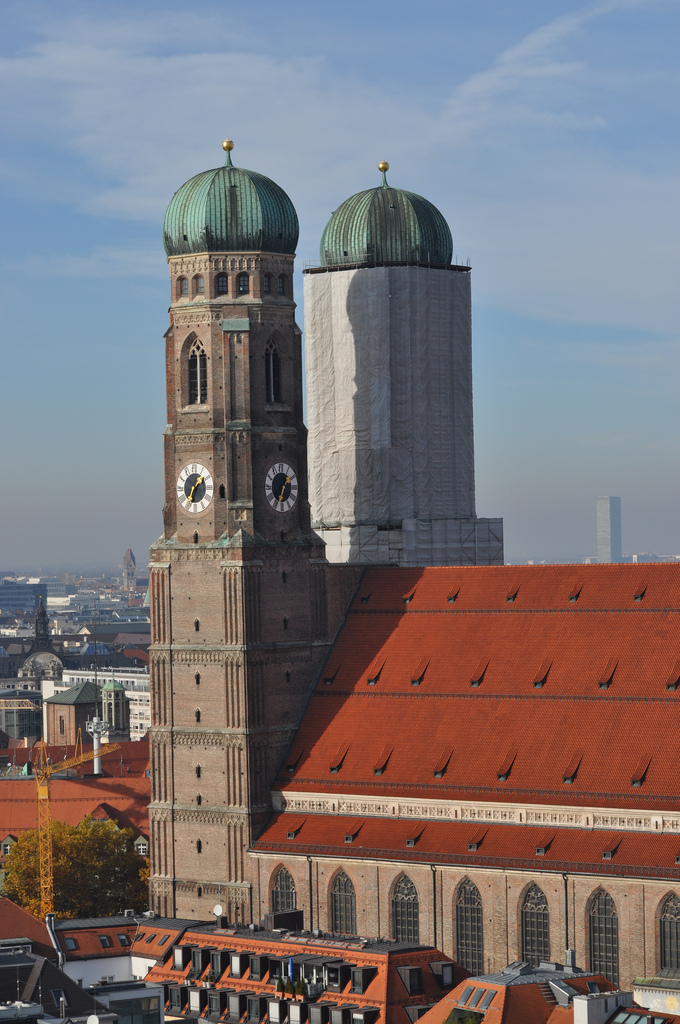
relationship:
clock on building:
[172, 459, 217, 524] [126, 129, 333, 977]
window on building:
[452, 874, 484, 976] [162, 131, 678, 985]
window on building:
[644, 896, 677, 981] [162, 131, 678, 985]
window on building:
[584, 881, 622, 992] [162, 131, 678, 985]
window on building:
[450, 871, 490, 973] [162, 131, 678, 985]